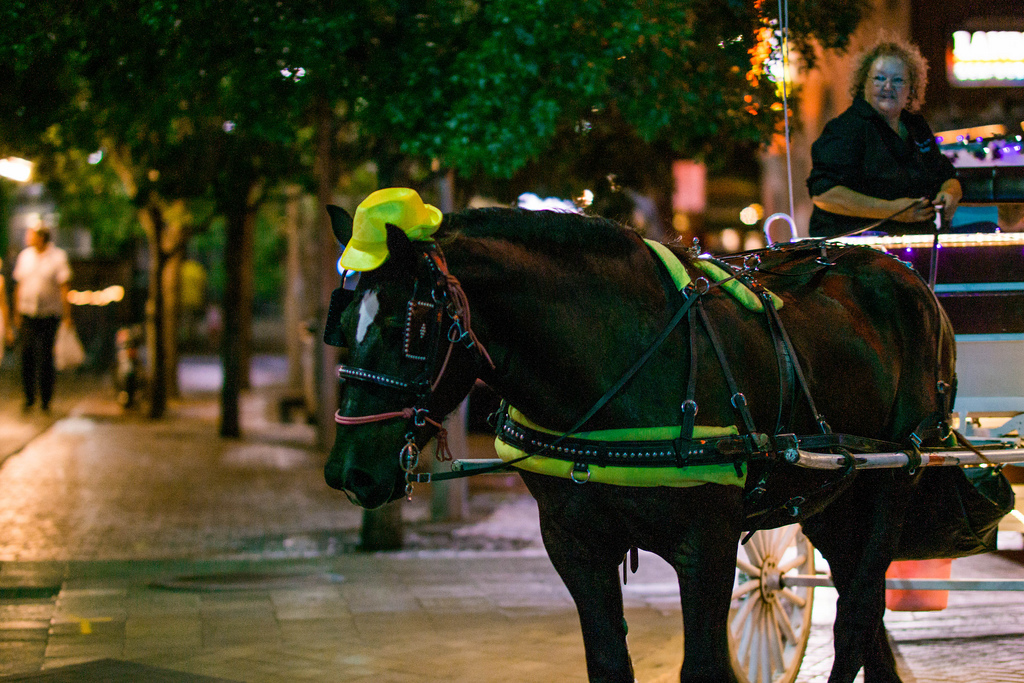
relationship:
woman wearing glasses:
[799, 39, 967, 244] [869, 59, 913, 90]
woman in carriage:
[799, 39, 967, 244] [698, 180, 1018, 630]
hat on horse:
[331, 172, 446, 281] [313, 204, 961, 676]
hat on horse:
[318, 172, 450, 296] [313, 204, 961, 676]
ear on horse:
[372, 204, 429, 271] [335, 204, 960, 676]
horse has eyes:
[313, 204, 961, 676] [313, 286, 460, 367]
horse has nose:
[313, 204, 961, 676] [318, 461, 385, 516]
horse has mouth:
[313, 204, 961, 676] [305, 455, 407, 505]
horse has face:
[335, 204, 960, 676] [318, 267, 431, 486]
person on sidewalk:
[13, 211, 72, 420] [0, 349, 113, 490]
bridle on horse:
[298, 278, 458, 460] [313, 204, 961, 676]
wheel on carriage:
[720, 490, 822, 678] [698, 133, 1012, 672]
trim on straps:
[633, 217, 787, 326] [616, 219, 852, 535]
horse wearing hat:
[313, 204, 961, 676] [324, 179, 458, 296]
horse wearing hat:
[313, 204, 961, 676] [326, 166, 452, 285]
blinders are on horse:
[303, 276, 466, 382] [313, 204, 961, 676]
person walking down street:
[15, 211, 89, 434] [6, 314, 1020, 678]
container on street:
[877, 543, 975, 621] [6, 314, 1020, 678]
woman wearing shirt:
[788, 25, 990, 259] [804, 107, 960, 233]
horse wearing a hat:
[313, 204, 961, 676] [309, 174, 465, 296]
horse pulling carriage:
[313, 204, 961, 676] [780, 60, 1018, 560]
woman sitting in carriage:
[799, 39, 967, 244] [765, 38, 1020, 598]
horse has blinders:
[313, 204, 961, 676] [296, 271, 489, 364]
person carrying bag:
[13, 211, 72, 420] [30, 293, 132, 419]